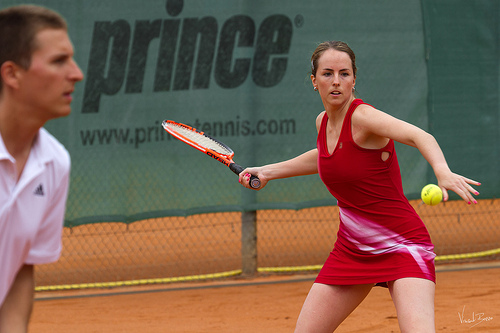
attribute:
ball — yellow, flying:
[421, 183, 444, 206]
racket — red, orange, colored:
[161, 119, 260, 189]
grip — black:
[229, 162, 260, 189]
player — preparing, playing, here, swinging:
[238, 42, 483, 333]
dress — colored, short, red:
[313, 99, 436, 286]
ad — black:
[80, 0, 304, 144]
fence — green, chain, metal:
[0, 1, 499, 228]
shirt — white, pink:
[0, 127, 72, 308]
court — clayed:
[1, 200, 498, 333]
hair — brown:
[311, 40, 357, 76]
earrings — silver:
[313, 86, 318, 91]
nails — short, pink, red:
[438, 180, 480, 204]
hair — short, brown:
[0, 5, 67, 69]